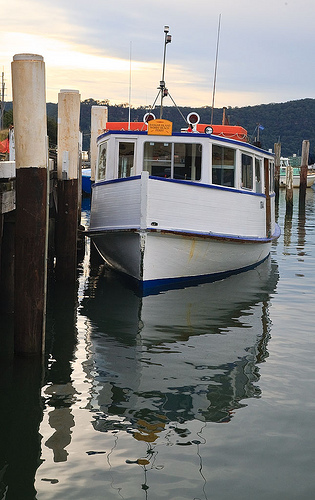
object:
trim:
[92, 174, 276, 200]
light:
[145, 114, 154, 124]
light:
[187, 112, 200, 125]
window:
[212, 143, 237, 188]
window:
[241, 153, 254, 188]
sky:
[0, 0, 314, 110]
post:
[299, 140, 309, 190]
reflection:
[78, 261, 281, 442]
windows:
[97, 140, 273, 191]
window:
[142, 141, 203, 181]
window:
[118, 142, 135, 179]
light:
[0, 0, 267, 112]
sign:
[147, 119, 172, 136]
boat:
[85, 13, 281, 297]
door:
[264, 157, 271, 238]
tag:
[147, 118, 172, 135]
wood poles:
[10, 52, 82, 357]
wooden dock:
[1, 153, 54, 232]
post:
[11, 52, 47, 358]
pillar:
[11, 53, 47, 356]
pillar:
[56, 89, 81, 284]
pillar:
[90, 105, 109, 182]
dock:
[10, 54, 50, 360]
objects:
[105, 121, 248, 139]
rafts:
[106, 121, 248, 142]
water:
[0, 184, 315, 500]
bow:
[110, 170, 188, 298]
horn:
[143, 112, 156, 131]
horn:
[186, 111, 200, 133]